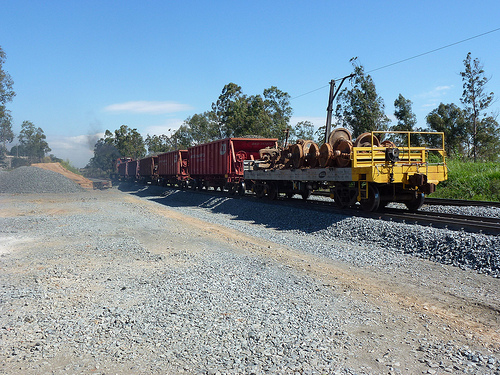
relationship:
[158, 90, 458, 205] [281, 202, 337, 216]
train has shadow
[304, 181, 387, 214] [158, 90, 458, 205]
wheel of train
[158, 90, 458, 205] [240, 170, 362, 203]
train on track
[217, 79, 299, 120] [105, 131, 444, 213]
tops visible over train